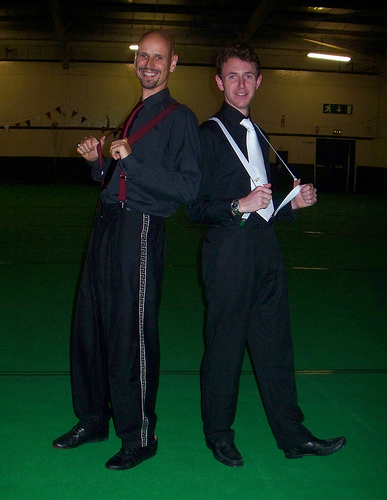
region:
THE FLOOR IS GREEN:
[182, 473, 197, 496]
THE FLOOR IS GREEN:
[188, 479, 200, 490]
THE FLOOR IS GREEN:
[182, 453, 189, 460]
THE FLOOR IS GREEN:
[196, 473, 209, 479]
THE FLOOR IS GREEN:
[185, 454, 197, 460]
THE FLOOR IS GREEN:
[200, 481, 208, 483]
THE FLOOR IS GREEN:
[201, 482, 210, 493]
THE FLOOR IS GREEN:
[195, 468, 213, 487]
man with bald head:
[93, 27, 195, 93]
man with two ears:
[121, 31, 192, 95]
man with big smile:
[96, 33, 200, 102]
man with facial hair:
[112, 19, 186, 101]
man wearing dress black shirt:
[65, 78, 197, 231]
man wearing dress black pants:
[45, 25, 189, 486]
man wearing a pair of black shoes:
[29, 21, 189, 480]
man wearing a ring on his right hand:
[48, 126, 172, 175]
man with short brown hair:
[199, 27, 295, 121]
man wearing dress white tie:
[196, 95, 294, 240]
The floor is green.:
[172, 470, 204, 496]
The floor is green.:
[188, 477, 204, 495]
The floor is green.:
[174, 434, 204, 466]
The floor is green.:
[167, 444, 213, 492]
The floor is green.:
[249, 480, 270, 498]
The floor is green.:
[209, 488, 220, 495]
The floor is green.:
[172, 463, 200, 486]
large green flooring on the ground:
[88, 471, 191, 498]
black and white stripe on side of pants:
[130, 380, 155, 451]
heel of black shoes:
[323, 427, 348, 456]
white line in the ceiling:
[299, 45, 365, 69]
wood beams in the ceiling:
[68, 8, 185, 22]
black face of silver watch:
[226, 198, 257, 219]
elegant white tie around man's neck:
[232, 115, 275, 223]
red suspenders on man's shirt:
[85, 93, 165, 164]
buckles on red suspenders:
[110, 171, 131, 208]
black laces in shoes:
[103, 441, 138, 457]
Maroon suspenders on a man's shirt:
[142, 101, 188, 133]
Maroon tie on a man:
[119, 102, 146, 138]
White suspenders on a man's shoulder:
[210, 114, 239, 156]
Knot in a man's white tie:
[239, 116, 256, 133]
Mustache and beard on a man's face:
[134, 67, 165, 89]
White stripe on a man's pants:
[135, 209, 152, 457]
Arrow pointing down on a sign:
[334, 103, 341, 114]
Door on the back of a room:
[314, 132, 354, 191]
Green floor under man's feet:
[5, 377, 383, 498]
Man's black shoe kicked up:
[277, 421, 345, 463]